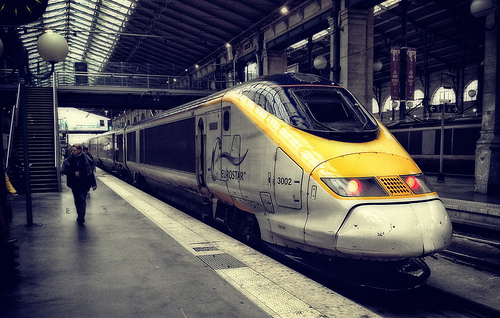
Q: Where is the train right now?
A: In the station.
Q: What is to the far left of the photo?
A: A staircase.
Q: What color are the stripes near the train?
A: White.